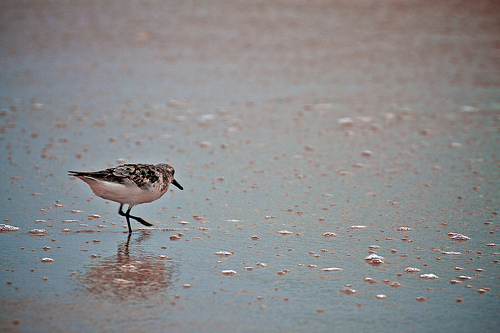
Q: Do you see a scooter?
A: No, there are no scooters.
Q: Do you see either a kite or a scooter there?
A: No, there are no scooters or kites.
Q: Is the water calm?
A: Yes, the water is calm.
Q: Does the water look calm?
A: Yes, the water is calm.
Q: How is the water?
A: The water is calm.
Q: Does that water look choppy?
A: No, the water is calm.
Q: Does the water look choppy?
A: No, the water is calm.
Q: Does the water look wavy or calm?
A: The water is calm.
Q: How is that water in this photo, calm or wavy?
A: The water is calm.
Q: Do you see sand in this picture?
A: Yes, there is sand.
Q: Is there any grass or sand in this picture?
A: Yes, there is sand.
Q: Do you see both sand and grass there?
A: No, there is sand but no grass.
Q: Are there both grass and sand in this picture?
A: No, there is sand but no grass.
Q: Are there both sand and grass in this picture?
A: No, there is sand but no grass.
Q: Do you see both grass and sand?
A: No, there is sand but no grass.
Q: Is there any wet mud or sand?
A: Yes, there is wet sand.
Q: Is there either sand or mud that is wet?
A: Yes, the sand is wet.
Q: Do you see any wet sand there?
A: Yes, there is wet sand.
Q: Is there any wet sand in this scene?
A: Yes, there is wet sand.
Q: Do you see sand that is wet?
A: Yes, there is sand that is wet.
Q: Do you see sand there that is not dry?
A: Yes, there is wet sand.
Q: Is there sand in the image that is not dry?
A: Yes, there is wet sand.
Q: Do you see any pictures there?
A: No, there are no pictures.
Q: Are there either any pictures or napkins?
A: No, there are no pictures or napkins.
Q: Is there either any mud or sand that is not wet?
A: No, there is sand but it is wet.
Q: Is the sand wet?
A: Yes, the sand is wet.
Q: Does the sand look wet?
A: Yes, the sand is wet.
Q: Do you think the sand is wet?
A: Yes, the sand is wet.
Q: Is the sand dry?
A: No, the sand is wet.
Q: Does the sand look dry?
A: No, the sand is wet.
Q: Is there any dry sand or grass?
A: No, there is sand but it is wet.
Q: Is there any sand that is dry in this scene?
A: No, there is sand but it is wet.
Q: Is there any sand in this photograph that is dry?
A: No, there is sand but it is wet.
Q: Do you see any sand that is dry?
A: No, there is sand but it is wet.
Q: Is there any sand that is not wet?
A: No, there is sand but it is wet.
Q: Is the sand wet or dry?
A: The sand is wet.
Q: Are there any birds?
A: Yes, there is a bird.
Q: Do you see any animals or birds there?
A: Yes, there is a bird.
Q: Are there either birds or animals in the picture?
A: Yes, there is a bird.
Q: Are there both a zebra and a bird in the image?
A: No, there is a bird but no zebras.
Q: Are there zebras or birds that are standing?
A: Yes, the bird is standing.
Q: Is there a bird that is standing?
A: Yes, there is a bird that is standing.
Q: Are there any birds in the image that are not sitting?
A: Yes, there is a bird that is standing.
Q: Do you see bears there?
A: No, there are no bears.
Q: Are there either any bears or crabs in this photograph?
A: No, there are no bears or crabs.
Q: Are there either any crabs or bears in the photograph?
A: No, there are no bears or crabs.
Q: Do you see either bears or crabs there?
A: No, there are no bears or crabs.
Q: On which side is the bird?
A: The bird is on the left of the image.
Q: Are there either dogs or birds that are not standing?
A: No, there is a bird but it is standing.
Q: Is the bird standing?
A: Yes, the bird is standing.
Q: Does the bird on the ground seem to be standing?
A: Yes, the bird is standing.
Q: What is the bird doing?
A: The bird is standing.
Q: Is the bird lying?
A: No, the bird is standing.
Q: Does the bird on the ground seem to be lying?
A: No, the bird is standing.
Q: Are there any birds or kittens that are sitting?
A: No, there is a bird but it is standing.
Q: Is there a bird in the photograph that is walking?
A: No, there is a bird but it is standing.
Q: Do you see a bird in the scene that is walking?
A: No, there is a bird but it is standing.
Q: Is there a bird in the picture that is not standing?
A: No, there is a bird but it is standing.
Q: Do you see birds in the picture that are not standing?
A: No, there is a bird but it is standing.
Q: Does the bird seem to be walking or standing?
A: The bird is standing.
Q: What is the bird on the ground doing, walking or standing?
A: The bird is standing.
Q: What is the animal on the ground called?
A: The animal is a bird.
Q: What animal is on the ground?
A: The animal is a bird.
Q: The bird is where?
A: The bird is on the ground.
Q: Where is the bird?
A: The bird is on the ground.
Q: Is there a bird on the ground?
A: Yes, there is a bird on the ground.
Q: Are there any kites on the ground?
A: No, there is a bird on the ground.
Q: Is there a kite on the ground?
A: No, there is a bird on the ground.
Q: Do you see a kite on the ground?
A: No, there is a bird on the ground.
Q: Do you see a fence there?
A: No, there are no fences.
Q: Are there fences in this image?
A: No, there are no fences.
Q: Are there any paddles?
A: No, there are no paddles.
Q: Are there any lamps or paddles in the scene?
A: No, there are no paddles or lamps.